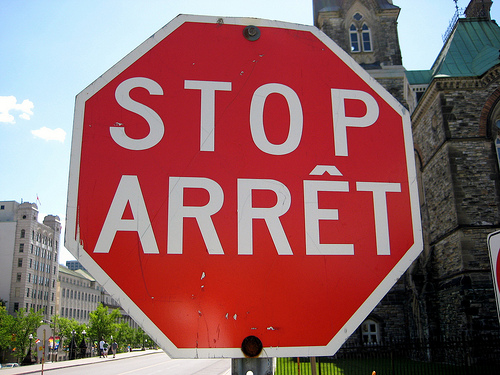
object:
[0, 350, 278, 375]
ground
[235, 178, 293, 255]
letter r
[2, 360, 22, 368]
car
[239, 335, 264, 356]
bolt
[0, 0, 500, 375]
photo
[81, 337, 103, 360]
people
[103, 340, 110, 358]
people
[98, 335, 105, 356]
people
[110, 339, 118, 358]
people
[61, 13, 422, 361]
sign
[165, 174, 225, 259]
r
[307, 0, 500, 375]
building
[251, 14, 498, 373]
building.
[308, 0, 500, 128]
roof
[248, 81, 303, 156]
letter "o"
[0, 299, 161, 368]
trees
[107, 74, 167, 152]
letter s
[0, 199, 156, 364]
building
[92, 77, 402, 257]
lettering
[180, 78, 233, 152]
letter t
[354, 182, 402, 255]
letter t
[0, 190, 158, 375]
background